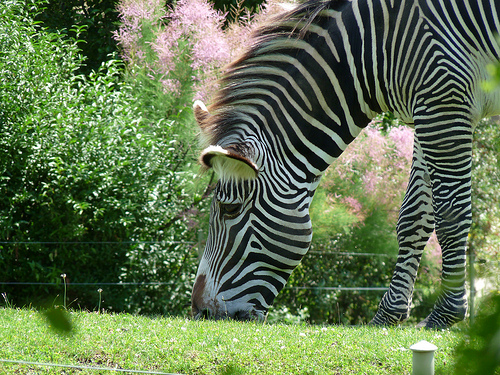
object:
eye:
[220, 202, 244, 215]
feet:
[365, 286, 414, 331]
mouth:
[222, 306, 260, 326]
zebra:
[184, 0, 500, 331]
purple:
[113, 0, 279, 85]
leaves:
[1, 4, 200, 316]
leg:
[415, 112, 480, 334]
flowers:
[147, 21, 188, 97]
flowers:
[185, 16, 231, 71]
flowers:
[341, 127, 414, 199]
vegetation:
[0, 0, 204, 320]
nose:
[189, 265, 215, 322]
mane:
[191, 0, 350, 204]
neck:
[211, 0, 388, 185]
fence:
[0, 234, 500, 333]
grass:
[0, 297, 500, 375]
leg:
[360, 125, 438, 326]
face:
[189, 178, 318, 326]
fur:
[192, 1, 500, 333]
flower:
[112, 0, 155, 48]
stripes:
[414, 121, 473, 134]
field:
[2, 304, 498, 374]